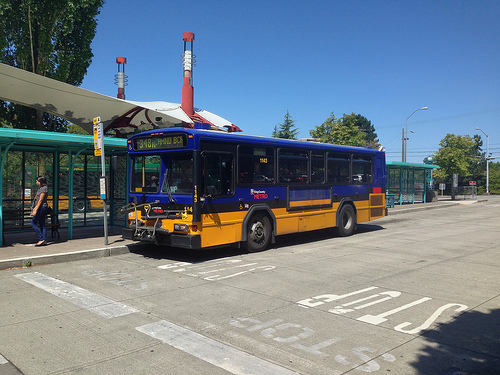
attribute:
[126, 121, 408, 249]
bus — blue, orange, green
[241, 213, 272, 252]
wheel — black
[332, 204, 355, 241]
wheel — black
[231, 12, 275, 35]
sky — blue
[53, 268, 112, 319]
line — white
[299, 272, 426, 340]
letters — white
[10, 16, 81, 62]
tree — green